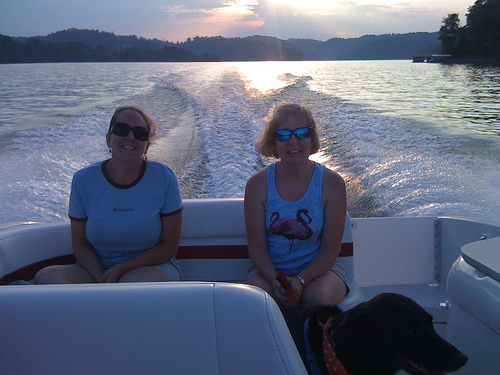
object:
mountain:
[333, 31, 443, 61]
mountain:
[174, 35, 303, 61]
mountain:
[0, 34, 202, 64]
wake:
[303, 89, 500, 217]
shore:
[0, 53, 430, 62]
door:
[352, 216, 437, 287]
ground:
[414, 155, 445, 175]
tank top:
[265, 161, 325, 276]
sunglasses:
[112, 121, 314, 138]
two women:
[35, 102, 351, 309]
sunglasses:
[273, 127, 311, 142]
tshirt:
[68, 158, 183, 268]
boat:
[1, 197, 500, 374]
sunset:
[154, 1, 267, 36]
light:
[150, 0, 358, 38]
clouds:
[0, 0, 477, 44]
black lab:
[277, 292, 469, 374]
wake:
[152, 71, 276, 199]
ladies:
[34, 104, 183, 283]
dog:
[282, 292, 469, 374]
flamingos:
[269, 208, 314, 256]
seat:
[0, 280, 309, 373]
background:
[0, 0, 497, 224]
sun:
[212, 0, 348, 18]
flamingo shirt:
[264, 161, 325, 278]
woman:
[244, 101, 351, 308]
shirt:
[68, 158, 183, 269]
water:
[0, 59, 500, 227]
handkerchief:
[318, 315, 351, 374]